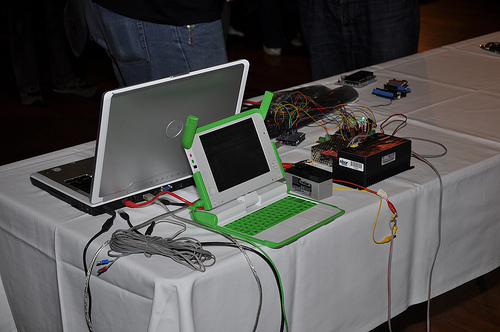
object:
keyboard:
[223, 195, 319, 236]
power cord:
[82, 209, 120, 332]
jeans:
[85, 2, 229, 89]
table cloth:
[0, 29, 500, 330]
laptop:
[181, 90, 345, 249]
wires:
[411, 151, 444, 332]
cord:
[116, 208, 283, 332]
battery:
[285, 162, 334, 202]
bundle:
[106, 227, 216, 272]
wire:
[332, 179, 399, 246]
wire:
[142, 194, 268, 332]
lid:
[90, 60, 250, 203]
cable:
[107, 218, 218, 273]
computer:
[28, 59, 250, 217]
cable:
[121, 190, 205, 209]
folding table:
[2, 30, 497, 330]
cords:
[329, 184, 395, 245]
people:
[79, 0, 230, 88]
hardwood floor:
[398, 291, 499, 330]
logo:
[165, 120, 185, 140]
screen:
[198, 117, 271, 193]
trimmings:
[31, 57, 251, 207]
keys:
[65, 174, 93, 193]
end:
[95, 266, 106, 275]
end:
[96, 259, 110, 266]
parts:
[250, 84, 411, 192]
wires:
[109, 220, 217, 277]